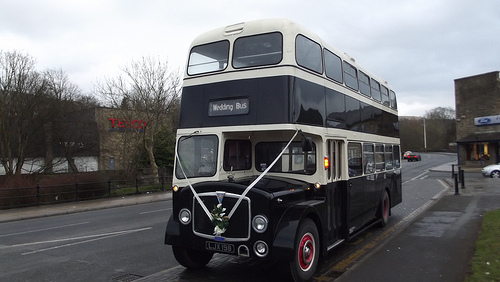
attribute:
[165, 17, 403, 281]
bus — black, large, double decker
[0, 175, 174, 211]
railing — black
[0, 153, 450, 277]
lines — white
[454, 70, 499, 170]
building — brown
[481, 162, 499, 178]
car — white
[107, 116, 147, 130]
sign — red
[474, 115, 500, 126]
sign — blue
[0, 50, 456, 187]
trees — bare